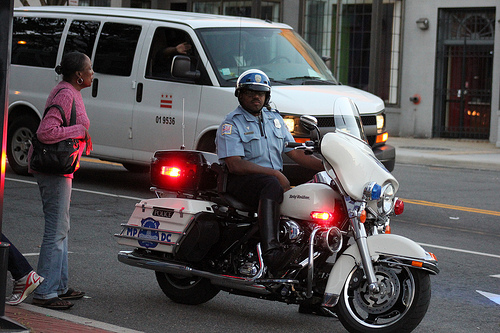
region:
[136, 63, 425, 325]
police man on motorcycle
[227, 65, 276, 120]
blue and white motorcycle helmet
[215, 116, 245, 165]
short sleeve of blue shirt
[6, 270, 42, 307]
running shoe with red trim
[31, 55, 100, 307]
woman in pink sweater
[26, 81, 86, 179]
large black shoulder bag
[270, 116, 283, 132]
police officer's shield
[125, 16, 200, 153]
door of white van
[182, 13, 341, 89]
front windshield of van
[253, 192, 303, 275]
man's tall black boot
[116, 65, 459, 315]
an officer on a motorcycle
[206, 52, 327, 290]
an african american police officer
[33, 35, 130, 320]
an elderly woman in a pink sweater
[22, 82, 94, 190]
a black leather purse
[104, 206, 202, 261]
the police department logo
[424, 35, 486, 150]
a decorative metal fence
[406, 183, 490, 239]
a yellow line in the road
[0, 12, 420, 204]
a white cargo van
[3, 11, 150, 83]
a row of windows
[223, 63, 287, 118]
a blue and white helmet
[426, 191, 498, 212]
Yellow solid line on street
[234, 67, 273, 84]
Blue and white helmet of police officer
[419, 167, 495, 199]
Small black section of the street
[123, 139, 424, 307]
White motorcycle of police officer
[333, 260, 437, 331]
Front tire of police officer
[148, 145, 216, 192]
One of the back headlights of the motorcycle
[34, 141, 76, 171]
Black purse of the female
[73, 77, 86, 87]
Right earring of female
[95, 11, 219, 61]
Small section of the white van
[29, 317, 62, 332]
Brick sidewalk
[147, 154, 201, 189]
red brake light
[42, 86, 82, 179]
black ladies handbag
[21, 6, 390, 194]
white passenger van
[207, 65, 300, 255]
police officer in uniform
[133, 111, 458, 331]
police officer motorcycle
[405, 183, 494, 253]
yellow lined painted in middle of street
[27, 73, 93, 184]
ladies pink sweater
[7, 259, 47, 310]
red and white tennis shoe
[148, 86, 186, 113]
red and white logo on side on van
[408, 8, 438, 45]
light attached to outside on building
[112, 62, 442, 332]
The police officer on the motorcycle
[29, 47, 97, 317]
The woman with the pink shirt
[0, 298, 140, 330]
The brick sidewalk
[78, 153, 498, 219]
The yellow line in the road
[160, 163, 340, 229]
The lit red lights on the motorcycle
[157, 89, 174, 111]
The red logo on the van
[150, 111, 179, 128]
The black numbers on the van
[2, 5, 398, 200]
The white van in the road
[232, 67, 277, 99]
The helmet of the officer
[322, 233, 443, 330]
The front tire of the motorcycle